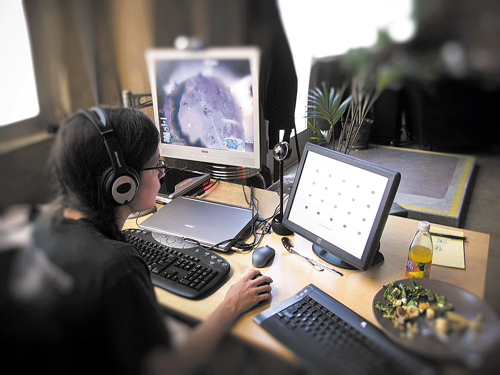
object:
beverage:
[403, 223, 434, 282]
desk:
[32, 155, 489, 374]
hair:
[49, 106, 160, 209]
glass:
[115, 156, 172, 173]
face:
[120, 138, 166, 210]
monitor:
[143, 43, 263, 172]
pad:
[151, 235, 200, 250]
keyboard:
[107, 226, 230, 299]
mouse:
[251, 245, 274, 268]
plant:
[264, 137, 290, 237]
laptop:
[137, 190, 261, 252]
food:
[380, 275, 492, 342]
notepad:
[418, 221, 466, 238]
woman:
[0, 101, 272, 375]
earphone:
[73, 103, 140, 207]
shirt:
[7, 209, 175, 375]